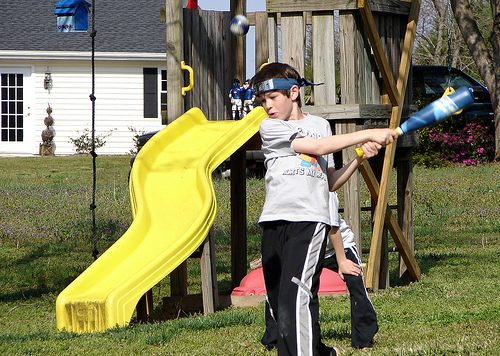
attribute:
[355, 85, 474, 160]
bat — blue, white, swinging, yellow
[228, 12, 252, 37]
ball — blue, silver, round, gray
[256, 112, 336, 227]
shirt — colorful, gray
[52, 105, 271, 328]
slide — yellow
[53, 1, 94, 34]
birdhouse — blue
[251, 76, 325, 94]
headband — blue, white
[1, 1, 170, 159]
house — white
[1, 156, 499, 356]
grass — brown, green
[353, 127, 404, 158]
handle — yellow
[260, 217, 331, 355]
pants — black,gray, white, black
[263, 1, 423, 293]
fort — wooden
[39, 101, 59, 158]
tree — decorative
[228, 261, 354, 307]
sandbox lid — red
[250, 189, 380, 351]
boy — crouching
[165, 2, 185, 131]
pole — wooden